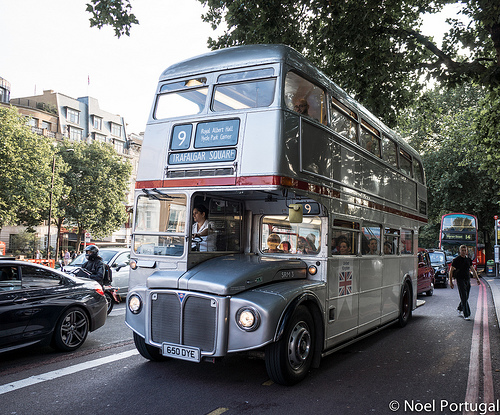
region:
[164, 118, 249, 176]
DESTINATION OF BUS ROUTE ON BUS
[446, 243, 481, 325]
MAN WALKING IN THE STREET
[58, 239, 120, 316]
PERSON ON MOTORCYCLE IN TRAFFIC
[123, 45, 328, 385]
FRONT OF DOUBLE DECKER BUS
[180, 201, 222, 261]
WOMAN BUS DRIVER BEHIND THE WHEEL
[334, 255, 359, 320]
NAME OF BUS COMPANY ON SIDE OF BUS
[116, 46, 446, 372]
GREY DOUBLE DECKER BUS IN TRAFFIC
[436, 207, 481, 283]
RED DOUBLE DECKER BUS NEAR BUS STOP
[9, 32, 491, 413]
DOUBLE DECKER BUS IN HEAVY TRAFFIC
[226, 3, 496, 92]
TREE LIMB HANGING OVER TOP OF DOUBLE DECKER BUS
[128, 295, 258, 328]
Bottom two illuminated headlights on a bus.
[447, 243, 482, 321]
A man in all black walking beside a bus.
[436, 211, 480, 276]
A double decker bus behind a man walking in traffic.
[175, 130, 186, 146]
A white number 9 on a silver double decker above TRAFALGAR.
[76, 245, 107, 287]
A person wearing a black helmet on a motorcycle.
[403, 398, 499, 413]
The name Noel Portugal.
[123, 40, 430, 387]
A silver double decker bus with license plate on front.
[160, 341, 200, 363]
License plate on a double decker bus that reads 650 DYE.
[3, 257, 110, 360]
A black car driving beside a silver bus.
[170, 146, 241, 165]
TRAFALGAR SQUARE on a double decker bus.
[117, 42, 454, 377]
an old grey bus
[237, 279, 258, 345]
the lights are on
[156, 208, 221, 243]
the driver is wearing white blouse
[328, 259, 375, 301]
the bus has a sticker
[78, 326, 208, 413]
the tarmac is marked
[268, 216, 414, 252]
the passangers are seated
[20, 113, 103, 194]
the trees are green in colour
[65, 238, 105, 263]
the helmet is black in collour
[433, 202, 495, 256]
the bus is red in colour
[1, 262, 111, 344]
the car is black in colour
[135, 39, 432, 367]
the bus is a doubledecker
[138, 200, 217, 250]
the driver is a woman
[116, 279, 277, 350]
the lights are on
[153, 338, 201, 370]
the number plate is white in colour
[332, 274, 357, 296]
it has a flag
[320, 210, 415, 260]
the windows are closed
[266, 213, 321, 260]
the passagers are seated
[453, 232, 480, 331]
a person is walking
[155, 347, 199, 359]
license plate on bus.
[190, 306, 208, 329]
grill on the bus.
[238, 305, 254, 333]
headlight on the bus.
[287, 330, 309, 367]
hubcap on the tire.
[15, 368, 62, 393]
white line on the road.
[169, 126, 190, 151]
number on the bus.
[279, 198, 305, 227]
mirror on the bus.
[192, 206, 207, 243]
driver of the bus.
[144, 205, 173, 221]
windshield of the bus.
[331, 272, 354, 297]
logo on the bus.